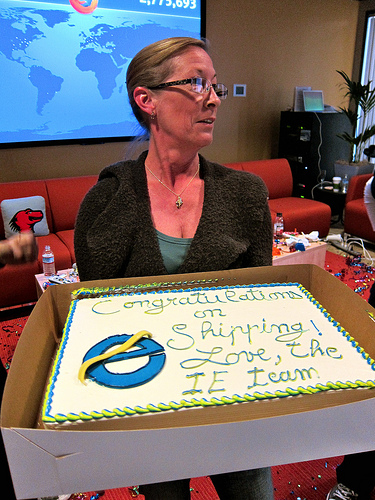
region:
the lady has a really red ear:
[124, 78, 165, 132]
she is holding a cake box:
[55, 275, 366, 422]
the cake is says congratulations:
[56, 282, 373, 411]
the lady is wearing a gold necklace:
[137, 161, 210, 222]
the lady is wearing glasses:
[132, 57, 253, 125]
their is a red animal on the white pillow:
[4, 201, 60, 244]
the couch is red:
[247, 167, 329, 235]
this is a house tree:
[334, 58, 374, 160]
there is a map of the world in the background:
[26, 12, 112, 138]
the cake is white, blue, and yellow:
[80, 278, 341, 417]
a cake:
[166, 315, 251, 428]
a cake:
[134, 331, 193, 409]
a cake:
[146, 311, 214, 384]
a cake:
[144, 339, 233, 465]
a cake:
[133, 359, 291, 495]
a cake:
[112, 294, 234, 413]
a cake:
[161, 372, 236, 433]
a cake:
[104, 358, 225, 441]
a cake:
[169, 385, 263, 493]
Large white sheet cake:
[38, 261, 367, 420]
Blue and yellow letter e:
[73, 320, 171, 396]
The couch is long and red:
[3, 152, 326, 260]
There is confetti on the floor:
[50, 448, 347, 495]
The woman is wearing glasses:
[80, 38, 287, 211]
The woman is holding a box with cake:
[30, 30, 334, 490]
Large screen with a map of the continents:
[6, 4, 206, 155]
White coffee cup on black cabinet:
[327, 168, 361, 204]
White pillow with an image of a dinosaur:
[3, 192, 61, 238]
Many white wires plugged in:
[322, 220, 369, 268]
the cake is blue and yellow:
[57, 288, 344, 395]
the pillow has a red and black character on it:
[2, 193, 62, 236]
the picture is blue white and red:
[9, 0, 190, 61]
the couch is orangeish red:
[262, 170, 291, 191]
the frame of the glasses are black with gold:
[156, 73, 203, 91]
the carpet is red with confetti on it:
[282, 468, 331, 495]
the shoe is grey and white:
[322, 476, 356, 498]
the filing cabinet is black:
[274, 102, 348, 195]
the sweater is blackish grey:
[219, 184, 250, 229]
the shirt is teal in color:
[163, 246, 180, 258]